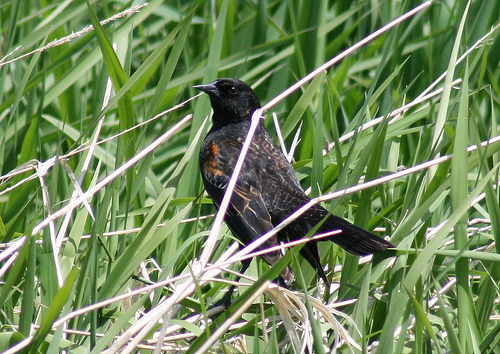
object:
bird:
[192, 76, 397, 313]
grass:
[0, 1, 499, 354]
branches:
[120, 1, 496, 317]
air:
[1, 2, 499, 73]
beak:
[192, 80, 221, 98]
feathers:
[197, 117, 297, 286]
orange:
[201, 142, 226, 176]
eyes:
[228, 85, 237, 95]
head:
[190, 77, 263, 118]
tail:
[320, 205, 396, 257]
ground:
[1, 218, 499, 352]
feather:
[299, 243, 331, 289]